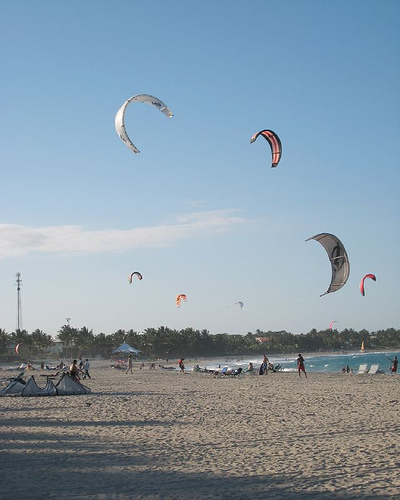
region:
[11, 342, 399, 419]
People on a beach.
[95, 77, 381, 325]
Kites flying in the air.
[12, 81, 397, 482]
People on a beach are flying kites.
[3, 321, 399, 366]
A line of trees along the beach.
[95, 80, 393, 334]
Several large kites in the air.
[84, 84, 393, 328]
The kites are all horseshoe shaped.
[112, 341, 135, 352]
The white tent top in the distance.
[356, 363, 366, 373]
The beach chair on the left.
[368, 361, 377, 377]
The beach chair on the right.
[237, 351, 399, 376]
The water in the distance.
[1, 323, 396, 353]
The trees in the distance.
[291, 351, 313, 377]
The person standing in front of the beach chairs.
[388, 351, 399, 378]
The person standing next to the beach chairs.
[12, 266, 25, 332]
The tower on the left.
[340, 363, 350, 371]
The two people in the water near the beach chairs.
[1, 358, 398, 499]
The sand area of the beach.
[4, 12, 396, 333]
blue sky broken by long and thin white cloud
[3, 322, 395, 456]
line of trees along edge of sandy beach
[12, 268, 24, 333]
tower topped with disk between balls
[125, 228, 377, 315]
curved kites flying in the air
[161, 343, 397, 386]
beach-goers rimming the edge of the shore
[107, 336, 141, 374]
person walking in front of open blue umbrella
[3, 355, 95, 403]
person standing behind segmented kite on sand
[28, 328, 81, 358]
flat white house partially hidden by trees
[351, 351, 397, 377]
man standing near curved beach chairs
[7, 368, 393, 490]
long shadows falling over patterned sand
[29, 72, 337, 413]
this is at a beach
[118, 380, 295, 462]
the beach is bumpy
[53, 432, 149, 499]
there are shadows on the beach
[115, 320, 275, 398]
there is a group of people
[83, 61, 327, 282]
these are kites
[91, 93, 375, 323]
the kites are flying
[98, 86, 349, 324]
the kites are u-shaped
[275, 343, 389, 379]
the water is blue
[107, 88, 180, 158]
white kite over sandy beach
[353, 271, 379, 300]
red kite over blue ocean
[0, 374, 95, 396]
three grey kites on sandy beach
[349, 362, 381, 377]
two beach chair on beach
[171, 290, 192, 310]
orange kite over sandy beach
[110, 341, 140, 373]
blue umbrella on beach by ocean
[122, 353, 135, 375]
man walking on beach towards ocean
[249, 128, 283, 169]
blue, white and red kite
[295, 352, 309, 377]
man standing in red swim shorts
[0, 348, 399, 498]
long stretch of sandy beach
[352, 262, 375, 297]
The kite is red.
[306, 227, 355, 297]
A large kite flying in the sky.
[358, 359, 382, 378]
Chairs in the sand by the water.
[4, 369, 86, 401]
Tents on the beach.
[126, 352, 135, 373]
A person walking towards the water.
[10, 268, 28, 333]
A large tower in the distance.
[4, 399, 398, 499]
The sand is brown.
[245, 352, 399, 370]
The water is blue.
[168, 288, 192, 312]
A yellow kite flying in the sky.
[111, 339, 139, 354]
A tent is on the beach.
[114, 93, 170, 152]
a large curved kite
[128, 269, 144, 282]
a large curved kite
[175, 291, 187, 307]
a large curved kite